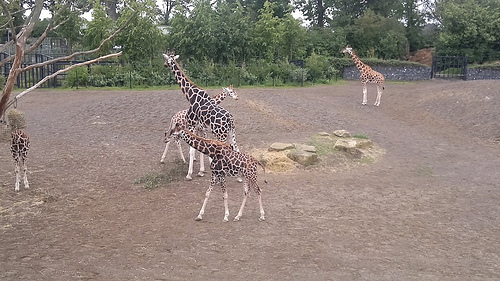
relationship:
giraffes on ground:
[156, 51, 267, 221] [2, 78, 499, 279]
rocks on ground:
[257, 127, 377, 163] [2, 78, 499, 279]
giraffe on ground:
[340, 44, 386, 107] [2, 78, 499, 279]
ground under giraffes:
[2, 78, 499, 279] [156, 51, 267, 221]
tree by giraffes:
[0, 0, 134, 124] [156, 51, 267, 221]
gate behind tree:
[7, 52, 60, 89] [0, 0, 134, 124]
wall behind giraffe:
[344, 60, 432, 82] [340, 44, 386, 107]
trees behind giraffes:
[62, 0, 340, 86] [156, 51, 267, 221]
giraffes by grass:
[156, 51, 267, 221] [47, 84, 333, 89]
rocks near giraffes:
[257, 127, 377, 163] [156, 51, 267, 221]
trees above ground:
[62, 0, 340, 86] [2, 78, 499, 279]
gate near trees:
[7, 52, 60, 89] [62, 0, 340, 86]